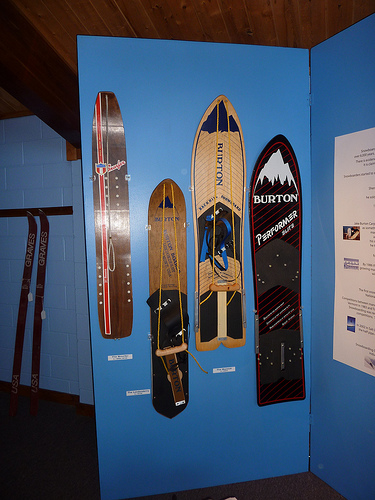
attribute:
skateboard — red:
[94, 92, 133, 338]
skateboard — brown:
[150, 179, 188, 421]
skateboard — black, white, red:
[250, 134, 305, 408]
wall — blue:
[1, 115, 96, 407]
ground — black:
[0, 391, 344, 499]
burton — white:
[254, 194, 299, 204]